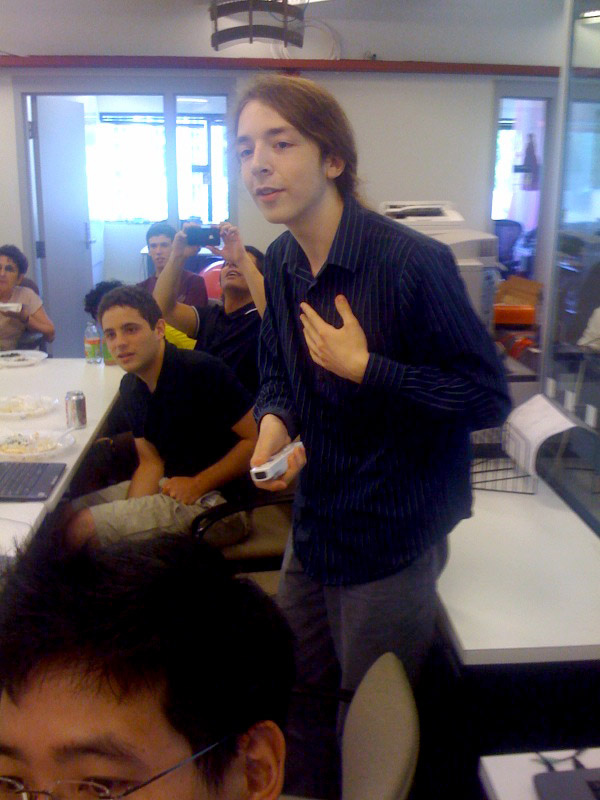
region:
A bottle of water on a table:
[84, 329, 97, 359]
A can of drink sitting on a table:
[66, 393, 85, 428]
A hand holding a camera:
[179, 227, 197, 254]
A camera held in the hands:
[187, 227, 217, 245]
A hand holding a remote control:
[258, 442, 293, 483]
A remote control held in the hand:
[268, 461, 286, 470]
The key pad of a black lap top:
[4, 464, 33, 494]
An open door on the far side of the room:
[45, 102, 81, 282]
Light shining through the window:
[97, 135, 163, 211]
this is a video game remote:
[238, 422, 321, 496]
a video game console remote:
[243, 436, 324, 490]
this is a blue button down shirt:
[233, 189, 511, 593]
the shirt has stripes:
[216, 206, 540, 590]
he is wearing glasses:
[0, 519, 313, 798]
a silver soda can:
[56, 380, 96, 429]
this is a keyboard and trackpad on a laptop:
[1, 451, 79, 511]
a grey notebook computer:
[4, 444, 77, 520]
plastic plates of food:
[5, 387, 92, 461]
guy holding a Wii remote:
[207, 93, 487, 790]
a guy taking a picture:
[159, 202, 277, 436]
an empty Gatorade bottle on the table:
[73, 320, 108, 383]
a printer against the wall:
[375, 187, 480, 245]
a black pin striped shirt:
[231, 218, 495, 568]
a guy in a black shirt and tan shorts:
[72, 354, 259, 548]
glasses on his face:
[0, 729, 265, 798]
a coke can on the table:
[66, 386, 93, 427]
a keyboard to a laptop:
[0, 461, 68, 497]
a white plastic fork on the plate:
[32, 422, 75, 450]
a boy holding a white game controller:
[251, 437, 310, 501]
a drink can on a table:
[59, 383, 87, 432]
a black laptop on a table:
[3, 454, 69, 507]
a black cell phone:
[182, 224, 220, 248]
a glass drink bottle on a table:
[82, 318, 106, 363]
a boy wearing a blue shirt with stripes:
[243, 217, 444, 467]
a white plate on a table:
[0, 349, 48, 368]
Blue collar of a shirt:
[279, 180, 377, 306]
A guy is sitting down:
[42, 270, 270, 576]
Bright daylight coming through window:
[72, 105, 234, 233]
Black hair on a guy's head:
[0, 522, 306, 792]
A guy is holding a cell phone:
[138, 207, 282, 405]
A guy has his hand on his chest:
[216, 60, 528, 444]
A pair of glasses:
[0, 728, 234, 794]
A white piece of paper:
[494, 381, 578, 489]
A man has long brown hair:
[224, 67, 380, 241]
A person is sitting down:
[41, 288, 270, 575]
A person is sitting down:
[150, 216, 301, 420]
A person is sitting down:
[123, 206, 219, 332]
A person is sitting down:
[0, 243, 70, 356]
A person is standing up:
[208, 85, 503, 749]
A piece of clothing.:
[94, 352, 254, 507]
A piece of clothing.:
[181, 292, 288, 380]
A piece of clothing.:
[225, 203, 509, 588]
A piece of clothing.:
[127, 256, 207, 317]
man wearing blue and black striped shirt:
[215, 82, 506, 637]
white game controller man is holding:
[247, 437, 303, 485]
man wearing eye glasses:
[6, 537, 283, 796]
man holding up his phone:
[145, 225, 265, 387]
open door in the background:
[38, 80, 184, 362]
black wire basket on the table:
[474, 403, 542, 498]